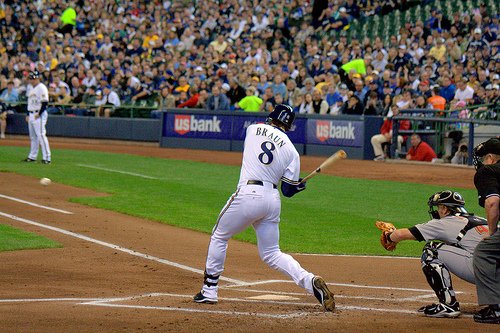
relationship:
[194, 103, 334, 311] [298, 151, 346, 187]
player swinging bat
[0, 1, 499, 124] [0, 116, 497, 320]
crowd watching game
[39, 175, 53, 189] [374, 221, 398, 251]
ball towards glove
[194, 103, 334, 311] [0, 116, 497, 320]
man playing baseball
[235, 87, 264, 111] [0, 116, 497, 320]
person watching game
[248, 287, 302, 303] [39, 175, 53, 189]
base and ball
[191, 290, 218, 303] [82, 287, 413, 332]
shoe on ground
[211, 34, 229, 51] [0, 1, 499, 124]
person in crowd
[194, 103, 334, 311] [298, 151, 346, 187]
player swings bat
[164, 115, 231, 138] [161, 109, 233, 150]
ad on backboard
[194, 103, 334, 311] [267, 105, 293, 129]
batter wearing helmet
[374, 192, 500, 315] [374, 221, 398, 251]
catcher wears mitt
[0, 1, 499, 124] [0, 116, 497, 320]
spectators watching game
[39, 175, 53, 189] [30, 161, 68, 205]
baseball in air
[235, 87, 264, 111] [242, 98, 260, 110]
person in shirt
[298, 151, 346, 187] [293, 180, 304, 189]
bat in hand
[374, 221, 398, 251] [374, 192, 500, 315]
glove on player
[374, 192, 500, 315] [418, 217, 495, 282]
player in gray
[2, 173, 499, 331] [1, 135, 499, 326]
dirt on field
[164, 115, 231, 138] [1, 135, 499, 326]
sign on field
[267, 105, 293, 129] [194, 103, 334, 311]
helmet on player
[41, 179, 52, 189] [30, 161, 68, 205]
baseball in air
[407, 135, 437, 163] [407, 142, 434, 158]
man in jacket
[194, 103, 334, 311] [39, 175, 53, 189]
player hitting ball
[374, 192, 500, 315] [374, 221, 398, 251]
catcher has mitt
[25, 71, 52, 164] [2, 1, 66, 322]
player on side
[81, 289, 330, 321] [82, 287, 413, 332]
lines on ground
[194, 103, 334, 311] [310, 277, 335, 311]
player has cleats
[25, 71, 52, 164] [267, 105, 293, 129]
player has helmet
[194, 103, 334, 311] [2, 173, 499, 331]
player on dirt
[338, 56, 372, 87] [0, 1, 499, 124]
vendor in stands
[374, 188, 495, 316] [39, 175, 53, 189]
catcher waits ball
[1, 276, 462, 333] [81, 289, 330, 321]
chalk makes lines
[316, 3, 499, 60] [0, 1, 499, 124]
area in stands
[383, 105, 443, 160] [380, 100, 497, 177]
men in dugout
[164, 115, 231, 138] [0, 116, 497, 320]
banner in game